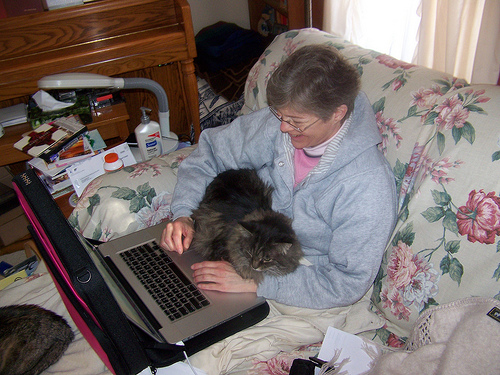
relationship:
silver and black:
[170, 320, 201, 338] [159, 274, 189, 300]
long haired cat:
[196, 210, 236, 234] [200, 166, 297, 281]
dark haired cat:
[225, 178, 251, 209] [200, 166, 297, 281]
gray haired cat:
[197, 214, 221, 235] [200, 166, 297, 281]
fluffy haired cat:
[205, 199, 247, 242] [200, 166, 297, 281]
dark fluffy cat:
[225, 178, 251, 209] [200, 166, 297, 281]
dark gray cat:
[225, 178, 251, 209] [200, 166, 297, 281]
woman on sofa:
[255, 38, 393, 298] [82, 34, 497, 337]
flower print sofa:
[404, 102, 498, 282] [82, 34, 497, 337]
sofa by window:
[82, 34, 497, 337] [317, 0, 495, 96]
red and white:
[102, 150, 117, 162] [104, 163, 127, 171]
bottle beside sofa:
[135, 111, 163, 160] [82, 34, 497, 337]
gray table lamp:
[55, 74, 168, 97] [35, 67, 180, 161]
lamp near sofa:
[35, 67, 180, 161] [82, 34, 497, 337]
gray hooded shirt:
[320, 142, 381, 275] [229, 117, 396, 264]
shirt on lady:
[229, 117, 396, 264] [255, 38, 393, 298]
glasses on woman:
[263, 105, 312, 138] [255, 38, 393, 298]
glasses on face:
[263, 105, 312, 138] [263, 93, 345, 146]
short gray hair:
[316, 63, 366, 127] [260, 43, 358, 125]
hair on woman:
[260, 43, 358, 125] [255, 38, 393, 298]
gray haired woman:
[298, 57, 334, 95] [255, 38, 393, 298]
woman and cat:
[255, 38, 393, 298] [200, 166, 297, 281]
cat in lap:
[200, 166, 297, 281] [127, 200, 376, 359]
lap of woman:
[127, 200, 376, 359] [255, 38, 393, 298]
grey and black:
[170, 320, 201, 338] [159, 274, 189, 300]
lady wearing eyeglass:
[255, 38, 393, 298] [263, 105, 312, 138]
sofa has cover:
[82, 34, 497, 337] [369, 51, 493, 356]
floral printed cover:
[404, 102, 498, 282] [369, 51, 493, 356]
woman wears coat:
[255, 38, 393, 298] [229, 117, 396, 264]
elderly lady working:
[271, 57, 375, 204] [153, 121, 251, 350]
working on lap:
[153, 121, 251, 350] [127, 261, 377, 360]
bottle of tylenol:
[96, 150, 128, 183] [103, 153, 130, 178]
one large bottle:
[105, 150, 126, 170] [96, 150, 128, 183]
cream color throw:
[444, 319, 492, 373] [371, 300, 495, 374]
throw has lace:
[371, 300, 495, 374] [406, 309, 434, 349]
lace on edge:
[406, 309, 434, 349] [355, 313, 415, 374]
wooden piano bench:
[100, 108, 127, 137] [3, 100, 132, 151]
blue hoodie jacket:
[311, 187, 365, 246] [229, 117, 396, 264]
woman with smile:
[255, 38, 393, 298] [281, 127, 316, 144]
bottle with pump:
[135, 111, 163, 160] [134, 104, 155, 128]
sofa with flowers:
[82, 34, 497, 337] [404, 102, 498, 282]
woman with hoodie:
[255, 38, 393, 298] [229, 117, 396, 264]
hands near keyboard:
[163, 220, 246, 303] [106, 231, 217, 336]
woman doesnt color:
[255, 38, 393, 298] [260, 43, 358, 125]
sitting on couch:
[127, 200, 376, 359] [82, 34, 497, 337]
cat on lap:
[200, 166, 297, 281] [127, 200, 376, 359]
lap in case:
[127, 261, 377, 360] [13, 171, 140, 369]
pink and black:
[35, 224, 50, 244] [82, 285, 113, 312]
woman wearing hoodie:
[255, 38, 393, 298] [229, 117, 396, 264]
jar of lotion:
[131, 108, 170, 167] [135, 111, 163, 160]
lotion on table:
[135, 111, 163, 160] [5, 144, 190, 194]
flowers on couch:
[405, 121, 499, 222] [82, 34, 497, 337]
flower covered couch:
[404, 102, 498, 282] [82, 34, 497, 337]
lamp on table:
[35, 67, 180, 161] [5, 144, 190, 194]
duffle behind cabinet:
[194, 18, 281, 86] [250, 2, 323, 37]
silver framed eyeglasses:
[271, 112, 323, 133] [263, 105, 312, 138]